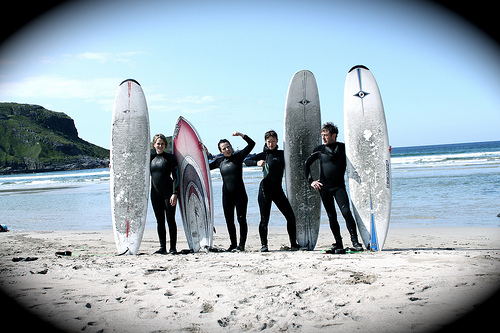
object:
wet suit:
[244, 143, 297, 246]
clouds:
[7, 50, 224, 115]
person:
[304, 121, 392, 252]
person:
[244, 129, 303, 252]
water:
[0, 136, 499, 232]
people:
[109, 133, 181, 254]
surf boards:
[109, 64, 392, 256]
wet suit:
[209, 134, 256, 247]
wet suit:
[304, 141, 359, 245]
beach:
[0, 228, 500, 333]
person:
[204, 131, 256, 253]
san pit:
[0, 232, 500, 333]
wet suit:
[149, 151, 180, 250]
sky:
[0, 0, 500, 156]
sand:
[0, 231, 500, 333]